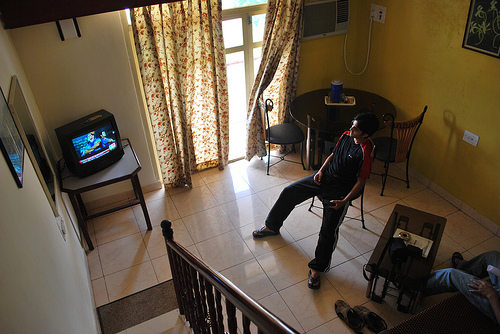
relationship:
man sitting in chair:
[252, 111, 379, 290] [309, 140, 377, 230]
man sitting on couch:
[394, 249, 499, 319] [372, 275, 499, 332]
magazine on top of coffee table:
[392, 226, 432, 255] [365, 201, 446, 313]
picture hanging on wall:
[7, 73, 57, 216] [1, 21, 102, 332]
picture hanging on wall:
[0, 88, 26, 189] [1, 21, 102, 332]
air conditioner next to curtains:
[300, 2, 352, 40] [241, 0, 301, 162]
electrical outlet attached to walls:
[369, 2, 388, 26] [366, 0, 498, 235]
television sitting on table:
[54, 108, 125, 179] [56, 136, 153, 251]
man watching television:
[252, 111, 379, 290] [54, 108, 125, 179]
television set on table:
[54, 108, 125, 179] [56, 136, 153, 251]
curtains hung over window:
[126, 1, 301, 190] [124, 1, 269, 168]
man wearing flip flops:
[252, 111, 379, 290] [250, 224, 322, 289]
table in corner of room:
[291, 87, 396, 173] [2, 0, 498, 333]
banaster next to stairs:
[161, 220, 304, 333] [115, 310, 201, 333]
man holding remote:
[252, 111, 379, 290] [320, 195, 336, 208]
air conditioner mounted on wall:
[300, 2, 352, 40] [295, 2, 356, 101]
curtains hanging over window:
[126, 1, 301, 190] [124, 1, 269, 168]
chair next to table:
[260, 94, 306, 177] [291, 87, 396, 173]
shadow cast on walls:
[376, 102, 498, 233] [366, 0, 498, 235]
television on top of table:
[54, 108, 125, 179] [56, 136, 153, 251]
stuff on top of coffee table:
[388, 224, 433, 273] [365, 201, 446, 313]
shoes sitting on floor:
[333, 296, 387, 332] [79, 144, 498, 333]